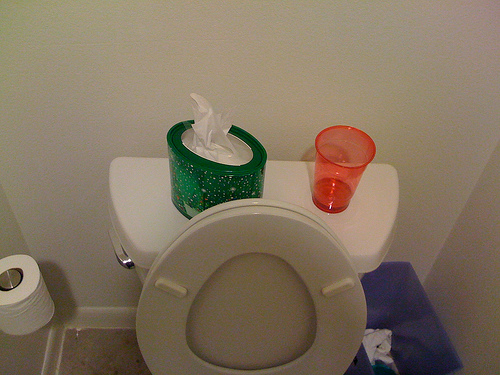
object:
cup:
[309, 122, 378, 214]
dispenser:
[164, 116, 269, 221]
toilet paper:
[0, 250, 60, 340]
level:
[105, 227, 136, 273]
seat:
[127, 198, 374, 374]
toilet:
[102, 155, 407, 374]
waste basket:
[343, 257, 467, 374]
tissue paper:
[178, 89, 256, 167]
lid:
[99, 154, 406, 275]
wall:
[2, 3, 499, 309]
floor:
[57, 321, 146, 375]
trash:
[361, 326, 406, 375]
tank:
[103, 151, 402, 287]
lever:
[107, 223, 137, 271]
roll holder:
[0, 267, 26, 292]